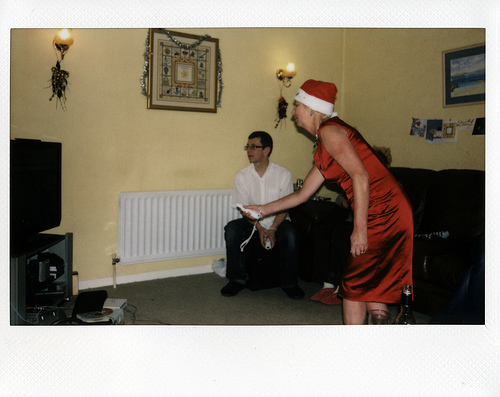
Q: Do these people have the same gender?
A: No, they are both male and female.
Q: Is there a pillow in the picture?
A: No, there are no pillows.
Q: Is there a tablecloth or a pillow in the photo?
A: No, there are no pillows or tablecloths.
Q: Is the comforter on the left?
A: Yes, the comforter is on the left of the image.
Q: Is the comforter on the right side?
A: No, the comforter is on the left of the image.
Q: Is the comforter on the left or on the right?
A: The comforter is on the left of the image.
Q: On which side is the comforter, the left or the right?
A: The comforter is on the left of the image.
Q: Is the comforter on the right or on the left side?
A: The comforter is on the left of the image.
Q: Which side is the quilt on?
A: The quilt is on the left of the image.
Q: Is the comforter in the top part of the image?
A: Yes, the comforter is in the top of the image.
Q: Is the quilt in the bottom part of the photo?
A: No, the quilt is in the top of the image.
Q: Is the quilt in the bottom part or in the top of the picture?
A: The quilt is in the top of the image.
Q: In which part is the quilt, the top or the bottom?
A: The quilt is in the top of the image.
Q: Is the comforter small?
A: Yes, the comforter is small.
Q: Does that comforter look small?
A: Yes, the comforter is small.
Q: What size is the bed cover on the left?
A: The bed cover is small.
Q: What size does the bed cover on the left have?
A: The bed cover has small size.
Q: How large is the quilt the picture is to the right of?
A: The quilt is small.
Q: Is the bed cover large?
A: No, the bed cover is small.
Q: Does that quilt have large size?
A: No, the quilt is small.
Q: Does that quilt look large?
A: No, the quilt is small.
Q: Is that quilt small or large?
A: The quilt is small.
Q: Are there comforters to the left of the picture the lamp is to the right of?
A: Yes, there is a comforter to the left of the picture.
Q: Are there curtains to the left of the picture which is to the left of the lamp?
A: No, there is a comforter to the left of the picture.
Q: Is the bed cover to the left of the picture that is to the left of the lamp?
A: Yes, the bed cover is to the left of the picture.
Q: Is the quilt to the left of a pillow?
A: No, the quilt is to the left of the picture.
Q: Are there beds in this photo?
A: No, there are no beds.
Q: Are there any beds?
A: No, there are no beds.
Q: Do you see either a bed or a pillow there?
A: No, there are no beds or pillows.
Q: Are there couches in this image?
A: Yes, there is a couch.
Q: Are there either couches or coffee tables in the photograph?
A: Yes, there is a couch.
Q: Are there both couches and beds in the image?
A: No, there is a couch but no beds.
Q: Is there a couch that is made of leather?
A: Yes, there is a couch that is made of leather.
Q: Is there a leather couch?
A: Yes, there is a couch that is made of leather.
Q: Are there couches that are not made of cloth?
A: Yes, there is a couch that is made of leather.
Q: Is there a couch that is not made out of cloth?
A: Yes, there is a couch that is made of leather.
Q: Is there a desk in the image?
A: No, there are no desks.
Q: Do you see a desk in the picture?
A: No, there are no desks.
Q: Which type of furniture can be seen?
A: The furniture is a couch.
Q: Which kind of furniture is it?
A: The piece of furniture is a couch.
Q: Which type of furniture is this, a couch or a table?
A: This is a couch.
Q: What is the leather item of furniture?
A: The piece of furniture is a couch.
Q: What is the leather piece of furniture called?
A: The piece of furniture is a couch.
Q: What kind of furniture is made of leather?
A: The furniture is a couch.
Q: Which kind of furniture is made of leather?
A: The furniture is a couch.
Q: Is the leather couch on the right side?
A: Yes, the couch is on the right of the image.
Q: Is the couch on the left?
A: No, the couch is on the right of the image.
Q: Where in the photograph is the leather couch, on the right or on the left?
A: The couch is on the right of the image.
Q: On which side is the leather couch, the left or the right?
A: The couch is on the right of the image.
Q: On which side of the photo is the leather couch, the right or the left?
A: The couch is on the right of the image.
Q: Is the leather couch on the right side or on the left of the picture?
A: The couch is on the right of the image.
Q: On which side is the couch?
A: The couch is on the right of the image.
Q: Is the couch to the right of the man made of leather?
A: Yes, the couch is made of leather.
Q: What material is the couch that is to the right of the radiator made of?
A: The couch is made of leather.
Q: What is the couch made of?
A: The couch is made of leather.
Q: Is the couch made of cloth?
A: No, the couch is made of leather.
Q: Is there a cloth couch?
A: No, there is a couch but it is made of leather.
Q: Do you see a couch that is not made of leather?
A: No, there is a couch but it is made of leather.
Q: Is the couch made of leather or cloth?
A: The couch is made of leather.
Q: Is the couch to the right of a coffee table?
A: No, the couch is to the right of a Wii controller.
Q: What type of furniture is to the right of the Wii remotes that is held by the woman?
A: The piece of furniture is a couch.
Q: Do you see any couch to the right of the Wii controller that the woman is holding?
A: Yes, there is a couch to the right of the Wii controller.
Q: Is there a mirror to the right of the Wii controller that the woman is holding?
A: No, there is a couch to the right of the Wii controller.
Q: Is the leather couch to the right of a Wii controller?
A: Yes, the couch is to the right of a Wii controller.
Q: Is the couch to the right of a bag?
A: No, the couch is to the right of a Wii controller.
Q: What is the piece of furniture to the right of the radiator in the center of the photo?
A: The piece of furniture is a couch.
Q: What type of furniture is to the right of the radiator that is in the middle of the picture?
A: The piece of furniture is a couch.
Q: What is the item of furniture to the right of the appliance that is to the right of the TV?
A: The piece of furniture is a couch.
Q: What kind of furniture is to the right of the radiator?
A: The piece of furniture is a couch.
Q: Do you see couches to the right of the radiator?
A: Yes, there is a couch to the right of the radiator.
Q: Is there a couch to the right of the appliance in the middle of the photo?
A: Yes, there is a couch to the right of the radiator.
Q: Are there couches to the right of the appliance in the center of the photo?
A: Yes, there is a couch to the right of the radiator.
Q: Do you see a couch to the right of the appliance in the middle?
A: Yes, there is a couch to the right of the radiator.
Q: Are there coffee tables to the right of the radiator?
A: No, there is a couch to the right of the radiator.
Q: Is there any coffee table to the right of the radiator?
A: No, there is a couch to the right of the radiator.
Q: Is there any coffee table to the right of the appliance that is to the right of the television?
A: No, there is a couch to the right of the radiator.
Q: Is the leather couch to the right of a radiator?
A: Yes, the couch is to the right of a radiator.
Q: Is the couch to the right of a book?
A: No, the couch is to the right of a radiator.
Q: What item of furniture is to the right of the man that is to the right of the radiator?
A: The piece of furniture is a couch.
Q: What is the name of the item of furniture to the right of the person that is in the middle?
A: The piece of furniture is a couch.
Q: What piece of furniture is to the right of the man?
A: The piece of furniture is a couch.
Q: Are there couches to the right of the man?
A: Yes, there is a couch to the right of the man.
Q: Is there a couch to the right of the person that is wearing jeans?
A: Yes, there is a couch to the right of the man.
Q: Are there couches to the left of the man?
A: No, the couch is to the right of the man.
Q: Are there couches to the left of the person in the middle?
A: No, the couch is to the right of the man.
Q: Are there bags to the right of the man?
A: No, there is a couch to the right of the man.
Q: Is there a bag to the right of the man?
A: No, there is a couch to the right of the man.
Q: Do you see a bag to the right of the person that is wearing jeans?
A: No, there is a couch to the right of the man.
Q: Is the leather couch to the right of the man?
A: Yes, the couch is to the right of the man.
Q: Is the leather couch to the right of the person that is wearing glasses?
A: Yes, the couch is to the right of the man.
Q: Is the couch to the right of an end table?
A: No, the couch is to the right of the man.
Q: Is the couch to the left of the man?
A: No, the couch is to the right of the man.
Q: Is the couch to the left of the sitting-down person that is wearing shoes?
A: No, the couch is to the right of the man.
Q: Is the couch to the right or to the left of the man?
A: The couch is to the right of the man.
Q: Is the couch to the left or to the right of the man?
A: The couch is to the right of the man.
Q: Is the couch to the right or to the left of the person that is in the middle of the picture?
A: The couch is to the right of the man.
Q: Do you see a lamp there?
A: Yes, there is a lamp.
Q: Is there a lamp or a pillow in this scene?
A: Yes, there is a lamp.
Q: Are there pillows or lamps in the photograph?
A: Yes, there is a lamp.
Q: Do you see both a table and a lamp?
A: No, there is a lamp but no tables.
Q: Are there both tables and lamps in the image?
A: No, there is a lamp but no tables.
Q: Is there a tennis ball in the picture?
A: No, there are no tennis balls.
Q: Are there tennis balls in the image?
A: No, there are no tennis balls.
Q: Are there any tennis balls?
A: No, there are no tennis balls.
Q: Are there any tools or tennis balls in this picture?
A: No, there are no tennis balls or tools.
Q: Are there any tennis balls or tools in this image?
A: No, there are no tennis balls or tools.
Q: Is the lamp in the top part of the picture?
A: Yes, the lamp is in the top of the image.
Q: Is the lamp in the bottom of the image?
A: No, the lamp is in the top of the image.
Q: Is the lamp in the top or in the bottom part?
A: The lamp is in the top of the image.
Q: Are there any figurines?
A: No, there are no figurines.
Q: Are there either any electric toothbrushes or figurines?
A: No, there are no figurines or electric toothbrushes.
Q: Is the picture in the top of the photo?
A: Yes, the picture is in the top of the image.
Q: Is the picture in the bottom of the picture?
A: No, the picture is in the top of the image.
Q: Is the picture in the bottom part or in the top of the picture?
A: The picture is in the top of the image.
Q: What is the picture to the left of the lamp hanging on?
A: The picture is hanging on the wall.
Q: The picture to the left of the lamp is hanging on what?
A: The picture is hanging on the wall.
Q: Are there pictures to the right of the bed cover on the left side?
A: Yes, there is a picture to the right of the quilt.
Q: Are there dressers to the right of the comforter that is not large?
A: No, there is a picture to the right of the comforter.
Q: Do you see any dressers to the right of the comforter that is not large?
A: No, there is a picture to the right of the comforter.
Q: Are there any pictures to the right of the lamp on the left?
A: Yes, there is a picture to the right of the lamp.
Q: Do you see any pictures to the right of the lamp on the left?
A: Yes, there is a picture to the right of the lamp.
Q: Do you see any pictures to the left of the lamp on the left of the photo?
A: No, the picture is to the right of the lamp.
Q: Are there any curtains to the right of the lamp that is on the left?
A: No, there is a picture to the right of the lamp.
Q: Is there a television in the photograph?
A: Yes, there is a television.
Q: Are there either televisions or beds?
A: Yes, there is a television.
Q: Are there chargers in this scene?
A: No, there are no chargers.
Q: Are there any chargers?
A: No, there are no chargers.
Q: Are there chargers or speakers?
A: No, there are no chargers or speakers.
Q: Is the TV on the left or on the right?
A: The TV is on the left of the image.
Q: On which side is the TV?
A: The TV is on the left of the image.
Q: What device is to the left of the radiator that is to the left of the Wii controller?
A: The device is a television.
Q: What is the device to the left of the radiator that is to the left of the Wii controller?
A: The device is a television.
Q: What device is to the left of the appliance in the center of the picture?
A: The device is a television.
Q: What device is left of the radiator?
A: The device is a television.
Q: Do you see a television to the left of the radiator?
A: Yes, there is a television to the left of the radiator.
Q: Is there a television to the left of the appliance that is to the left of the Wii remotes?
A: Yes, there is a television to the left of the radiator.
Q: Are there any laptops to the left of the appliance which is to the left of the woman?
A: No, there is a television to the left of the radiator.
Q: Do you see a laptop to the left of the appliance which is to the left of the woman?
A: No, there is a television to the left of the radiator.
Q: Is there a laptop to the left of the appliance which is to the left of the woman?
A: No, there is a television to the left of the radiator.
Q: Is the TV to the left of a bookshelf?
A: No, the TV is to the left of the radiator.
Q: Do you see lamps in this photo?
A: Yes, there is a lamp.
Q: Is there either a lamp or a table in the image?
A: Yes, there is a lamp.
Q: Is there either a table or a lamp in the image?
A: Yes, there is a lamp.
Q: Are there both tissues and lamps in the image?
A: No, there is a lamp but no tissues.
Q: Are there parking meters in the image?
A: No, there are no parking meters.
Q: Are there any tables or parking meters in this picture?
A: No, there are no parking meters or tables.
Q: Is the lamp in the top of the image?
A: Yes, the lamp is in the top of the image.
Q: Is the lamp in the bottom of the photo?
A: No, the lamp is in the top of the image.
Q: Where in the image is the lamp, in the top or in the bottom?
A: The lamp is in the top of the image.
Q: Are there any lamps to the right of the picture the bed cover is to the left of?
A: Yes, there is a lamp to the right of the picture.